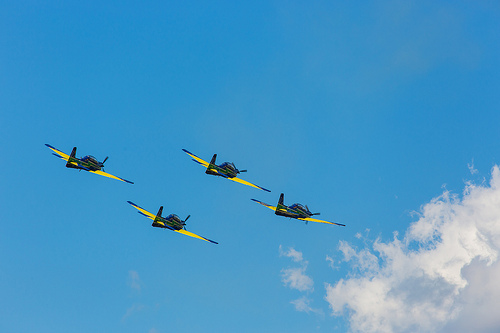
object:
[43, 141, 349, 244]
four planes in sky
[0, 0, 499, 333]
blue sky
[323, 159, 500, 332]
fluffy white cloud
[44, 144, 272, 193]
two planes flying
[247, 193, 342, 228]
flying toward cloud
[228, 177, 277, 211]
two plane wings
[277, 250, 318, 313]
clouds drifting away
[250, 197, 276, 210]
wing is sharp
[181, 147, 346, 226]
two planes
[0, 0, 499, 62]
high above the cloud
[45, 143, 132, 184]
jets has yellow wing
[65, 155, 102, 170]
body of jet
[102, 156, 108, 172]
propeller on front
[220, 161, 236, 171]
dome over cockpit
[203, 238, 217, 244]
dark tip of wing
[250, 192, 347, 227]
plane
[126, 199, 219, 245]
plane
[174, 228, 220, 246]
wings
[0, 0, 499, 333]
air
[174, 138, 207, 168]
wing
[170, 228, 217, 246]
wing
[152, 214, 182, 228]
body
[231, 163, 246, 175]
propeller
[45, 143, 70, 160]
wing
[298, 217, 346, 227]
wing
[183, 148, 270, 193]
jet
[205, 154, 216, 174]
tail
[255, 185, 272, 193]
tip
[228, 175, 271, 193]
wing